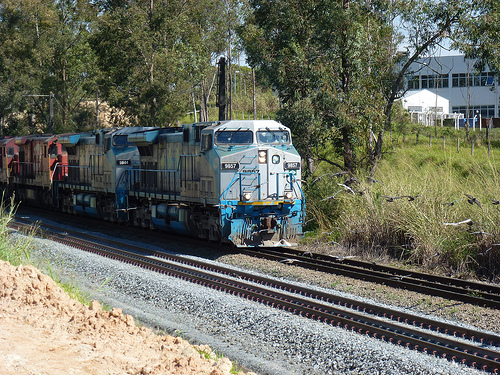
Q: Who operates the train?
A: The engineer.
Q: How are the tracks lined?
A: With gravel.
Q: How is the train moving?
A: Slowly.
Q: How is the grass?
A: Overgrown.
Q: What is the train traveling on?
A: Tracks.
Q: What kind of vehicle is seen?
A: Train.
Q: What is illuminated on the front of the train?
A: Lights.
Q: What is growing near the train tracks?
A: Trees.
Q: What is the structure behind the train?
A: Building.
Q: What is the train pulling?
A: Cars.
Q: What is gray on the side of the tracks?
A: Gravel.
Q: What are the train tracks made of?
A: Metal and wood.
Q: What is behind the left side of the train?
A: Trees.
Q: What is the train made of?
A: Metal.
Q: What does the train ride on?
A: Tracks.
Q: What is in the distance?
A: A building.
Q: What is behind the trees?
A: A field.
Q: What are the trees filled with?
A: Leaves.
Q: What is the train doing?
A: Passing by.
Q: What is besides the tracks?
A: Gravel.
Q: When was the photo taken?
A: Daytime.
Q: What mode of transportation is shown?
A: Train.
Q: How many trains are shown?
A: One.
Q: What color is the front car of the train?
A: Gray and blue.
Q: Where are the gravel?
A: Around the tracks.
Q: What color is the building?
A: White.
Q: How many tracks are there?
A: Two.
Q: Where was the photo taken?
A: On a railroad.